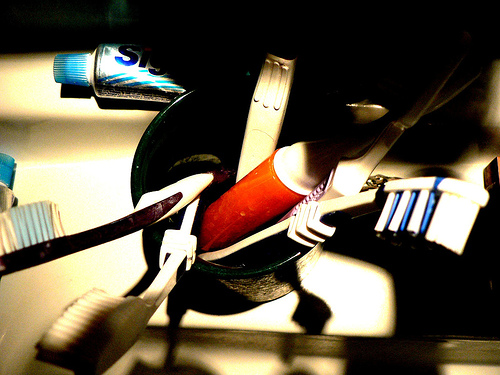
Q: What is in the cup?
A: Toothbrushes.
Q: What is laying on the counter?
A: Toothpaste.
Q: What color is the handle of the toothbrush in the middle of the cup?
A: Orange.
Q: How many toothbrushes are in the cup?
A: 6.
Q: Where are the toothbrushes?
A: In the cup.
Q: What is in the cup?
A: Tooth brushes.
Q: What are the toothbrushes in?
A: A cup.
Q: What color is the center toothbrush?
A: Red and white.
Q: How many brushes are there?
A: Six.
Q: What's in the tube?
A: Toothpaste.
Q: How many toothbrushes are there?
A: 6.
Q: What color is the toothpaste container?
A: Blue and White.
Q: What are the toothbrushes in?
A: A cup.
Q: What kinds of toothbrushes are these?
A: Manual.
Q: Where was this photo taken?
A: Bathroom.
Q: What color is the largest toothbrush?
A: Orange.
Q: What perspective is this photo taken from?
A: Top Down.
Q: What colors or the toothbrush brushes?
A: White and Blue.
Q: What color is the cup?
A: Black.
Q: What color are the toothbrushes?
A: Black.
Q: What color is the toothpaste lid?
A: Blue.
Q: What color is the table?
A: White.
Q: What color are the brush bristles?
A: White.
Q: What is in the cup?
A: Toothbrushes.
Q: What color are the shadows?
A: Black.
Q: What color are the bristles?
A: White.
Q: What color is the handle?
A: Black.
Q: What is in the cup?
A: Toothbrushes.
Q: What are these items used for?
A: Brushing teeth.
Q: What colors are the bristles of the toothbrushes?
A: White and blue.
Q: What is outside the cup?
A: Tubes of toothpaste.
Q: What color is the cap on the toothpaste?
A: Blue.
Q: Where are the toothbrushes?
A: In a cup.